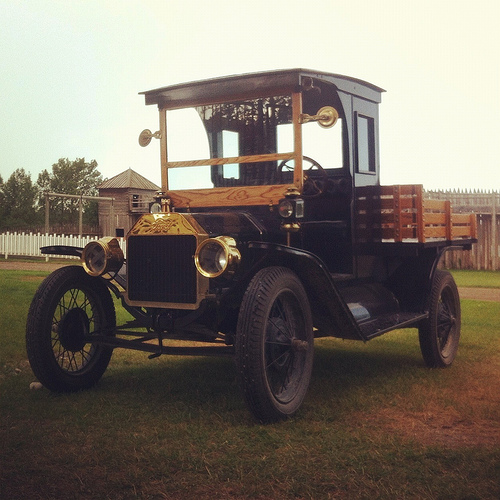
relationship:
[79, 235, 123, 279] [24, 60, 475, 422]
headlight on car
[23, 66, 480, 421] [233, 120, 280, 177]
antique car has a curtain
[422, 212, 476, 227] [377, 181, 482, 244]
slats on tailgate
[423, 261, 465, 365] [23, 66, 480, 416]
tire on antique car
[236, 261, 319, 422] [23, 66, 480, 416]
tire on antique car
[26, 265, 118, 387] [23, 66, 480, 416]
tire on antique car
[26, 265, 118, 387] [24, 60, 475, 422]
tire on car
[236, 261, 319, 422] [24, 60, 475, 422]
tire on car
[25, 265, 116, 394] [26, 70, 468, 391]
tire on car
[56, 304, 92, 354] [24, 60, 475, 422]
plate on car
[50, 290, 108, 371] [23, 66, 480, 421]
spokes on antique car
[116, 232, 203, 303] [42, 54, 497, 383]
grill on car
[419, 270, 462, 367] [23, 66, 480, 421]
tire on antique car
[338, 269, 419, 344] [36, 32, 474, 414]
step on car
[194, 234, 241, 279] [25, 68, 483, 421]
headlight on truck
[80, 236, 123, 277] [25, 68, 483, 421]
headlight on truck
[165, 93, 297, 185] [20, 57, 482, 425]
window on trucks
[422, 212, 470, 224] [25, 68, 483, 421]
slats on truck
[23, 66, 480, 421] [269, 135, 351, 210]
antique car has a steering wheel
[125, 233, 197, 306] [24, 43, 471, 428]
grill on truck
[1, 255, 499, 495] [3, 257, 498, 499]
ground covered with grass